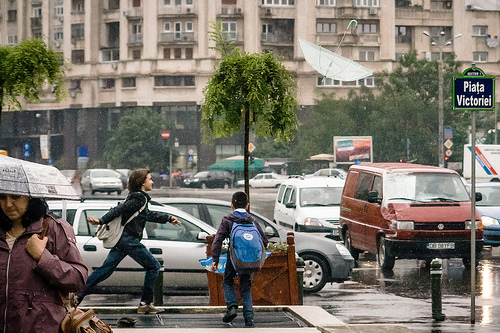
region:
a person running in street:
[76, 165, 179, 315]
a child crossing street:
[210, 188, 270, 325]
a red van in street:
[340, 162, 483, 270]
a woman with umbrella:
[0, 151, 109, 330]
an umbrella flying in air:
[300, 18, 372, 83]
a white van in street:
[272, 177, 342, 242]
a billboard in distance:
[331, 134, 373, 164]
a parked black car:
[180, 168, 230, 187]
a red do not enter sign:
[159, 129, 169, 139]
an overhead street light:
[420, 26, 463, 165]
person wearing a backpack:
[230, 223, 273, 273]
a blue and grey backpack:
[229, 225, 265, 267]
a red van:
[336, 165, 473, 248]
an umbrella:
[1, 159, 79, 201]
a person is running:
[91, 173, 166, 309]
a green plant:
[203, 53, 297, 134]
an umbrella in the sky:
[296, 30, 373, 85]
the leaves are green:
[2, 48, 64, 98]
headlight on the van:
[396, 219, 413, 232]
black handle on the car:
[148, 243, 165, 255]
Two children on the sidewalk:
[74, 164, 272, 329]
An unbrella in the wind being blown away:
[295, 17, 377, 89]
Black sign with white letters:
[448, 59, 499, 114]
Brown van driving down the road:
[335, 160, 487, 276]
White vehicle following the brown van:
[270, 171, 350, 245]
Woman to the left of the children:
[0, 148, 91, 331]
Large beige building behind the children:
[0, 0, 499, 103]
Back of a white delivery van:
[460, 141, 498, 190]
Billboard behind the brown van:
[330, 132, 375, 166]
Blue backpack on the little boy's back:
[223, 209, 268, 276]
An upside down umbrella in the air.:
[296, 18, 378, 90]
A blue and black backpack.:
[227, 222, 264, 275]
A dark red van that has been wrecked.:
[337, 160, 484, 267]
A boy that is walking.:
[82, 167, 183, 316]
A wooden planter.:
[203, 232, 303, 308]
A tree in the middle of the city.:
[200, 20, 299, 212]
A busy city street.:
[271, 159, 497, 331]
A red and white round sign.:
[158, 127, 173, 143]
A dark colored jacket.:
[89, 190, 171, 240]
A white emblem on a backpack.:
[242, 231, 254, 242]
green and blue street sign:
[451, 65, 495, 110]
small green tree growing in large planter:
[201, 21, 298, 141]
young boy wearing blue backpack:
[209, 190, 269, 327]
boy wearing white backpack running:
[74, 168, 181, 315]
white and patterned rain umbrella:
[0, 153, 86, 201]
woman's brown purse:
[61, 292, 113, 332]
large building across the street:
[0, 0, 499, 172]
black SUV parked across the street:
[181, 168, 232, 190]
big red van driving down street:
[338, 162, 485, 272]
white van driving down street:
[271, 178, 345, 239]